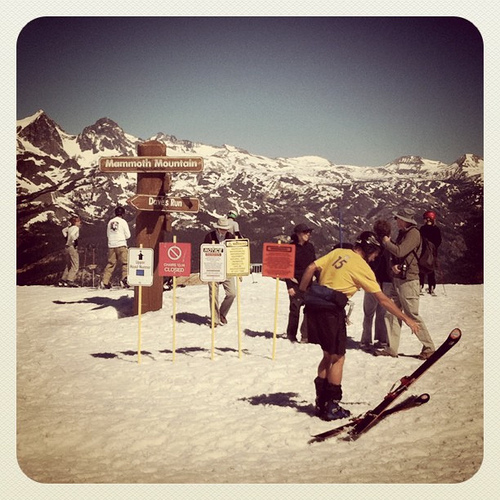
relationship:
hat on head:
[395, 205, 420, 227] [388, 206, 418, 232]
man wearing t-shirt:
[92, 202, 132, 292] [107, 217, 130, 249]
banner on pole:
[261, 242, 295, 277] [271, 274, 279, 361]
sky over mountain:
[15, 16, 483, 171] [20, 101, 481, 279]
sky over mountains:
[44, 30, 445, 122] [21, 106, 473, 188]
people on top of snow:
[57, 210, 129, 285] [29, 310, 454, 450]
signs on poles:
[94, 216, 274, 297] [125, 278, 281, 362]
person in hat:
[199, 217, 239, 330] [207, 210, 234, 232]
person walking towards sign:
[199, 217, 239, 330] [216, 233, 258, 283]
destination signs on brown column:
[96, 142, 206, 174] [126, 129, 171, 311]